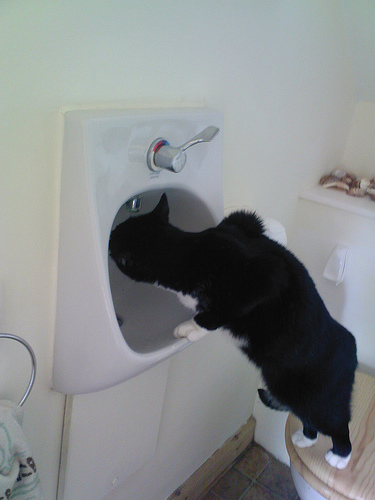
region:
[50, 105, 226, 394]
cat drinking from urinal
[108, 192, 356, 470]
black and white cat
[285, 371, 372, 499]
wood seat on toilet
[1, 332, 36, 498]
metal ring with towel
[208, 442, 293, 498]
colored tiles on floor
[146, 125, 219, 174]
handle on metal hardware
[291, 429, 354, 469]
white feet on black legs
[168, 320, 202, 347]
white paw on porcelain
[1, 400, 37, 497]
towel with black and green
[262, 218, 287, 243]
edge of white toilet paper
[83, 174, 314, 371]
a cat has his head in the dryer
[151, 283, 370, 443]
the cat is standing on the toilet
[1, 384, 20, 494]
a towel is on the rack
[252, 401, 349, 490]
the toilet is made of wood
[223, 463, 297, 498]
the floor is made of tile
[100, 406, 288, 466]
the floorboard is made of wood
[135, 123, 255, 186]
a knob is on the sink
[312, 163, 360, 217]
items are on top of the toilet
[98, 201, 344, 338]
the cat is black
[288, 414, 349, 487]
the cat has white feet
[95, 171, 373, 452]
Black cat with white feet.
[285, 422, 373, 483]
White feet on the cat.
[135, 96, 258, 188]
Handle on the appliance.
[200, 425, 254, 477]
Wood baseboard by the floor.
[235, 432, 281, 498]
Tile floor.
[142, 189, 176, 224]
Ear on the black cat.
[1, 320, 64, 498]
Towel on the towel rack.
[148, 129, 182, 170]
Red and blue for hot and cold.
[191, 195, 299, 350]
Fur on the cat.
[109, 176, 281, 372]
Cat with white front feet.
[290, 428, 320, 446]
the cats right paw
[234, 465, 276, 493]
tile on the floor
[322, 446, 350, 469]
the cats left paw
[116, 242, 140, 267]
the cats ear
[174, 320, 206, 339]
the cats paw is white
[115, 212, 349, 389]
a black and white cat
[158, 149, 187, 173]
a silver knob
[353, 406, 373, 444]
a wooden toilet seat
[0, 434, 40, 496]
a towel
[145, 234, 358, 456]
cat is standing on the toilet seat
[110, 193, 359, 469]
the animal is a cat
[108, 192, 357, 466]
cat is black and white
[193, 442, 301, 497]
the flooring is tile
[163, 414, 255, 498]
baseboard is unpainted wood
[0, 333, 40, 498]
metal hoop holding towel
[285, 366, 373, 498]
wooden toilet seat lid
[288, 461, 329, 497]
toilet seat is white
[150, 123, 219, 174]
handle is made of metal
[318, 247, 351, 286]
white handle on toilet tank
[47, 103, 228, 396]
cat is drinking from white sink